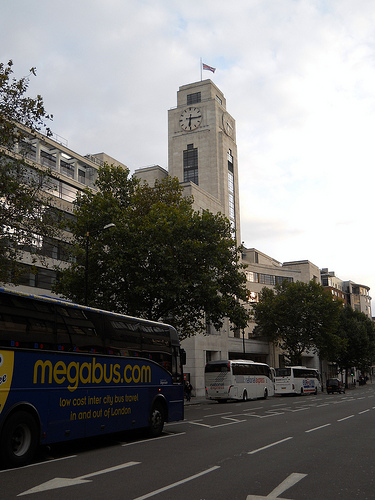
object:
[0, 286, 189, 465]
bus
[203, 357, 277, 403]
bus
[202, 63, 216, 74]
flag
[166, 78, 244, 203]
tower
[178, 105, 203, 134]
clock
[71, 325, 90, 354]
window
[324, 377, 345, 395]
car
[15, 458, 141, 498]
arrow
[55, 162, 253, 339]
tree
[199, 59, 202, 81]
pole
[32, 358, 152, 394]
ad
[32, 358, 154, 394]
megabus.com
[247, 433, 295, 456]
line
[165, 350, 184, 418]
door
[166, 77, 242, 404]
building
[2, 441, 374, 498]
road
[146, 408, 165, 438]
wheel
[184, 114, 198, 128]
face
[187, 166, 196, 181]
window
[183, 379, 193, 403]
person